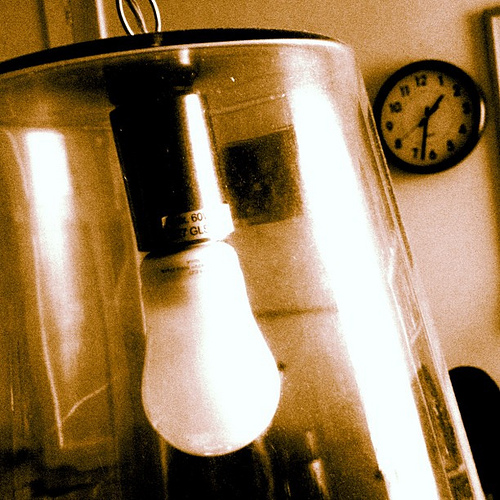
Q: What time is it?
A: About 1:30.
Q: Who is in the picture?
A: No one.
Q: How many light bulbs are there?
A: One.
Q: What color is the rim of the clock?
A: Black.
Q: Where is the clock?
A: On the wall.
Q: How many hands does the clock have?
A: Three.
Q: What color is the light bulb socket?
A: Black.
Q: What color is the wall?
A: Beige/tan.